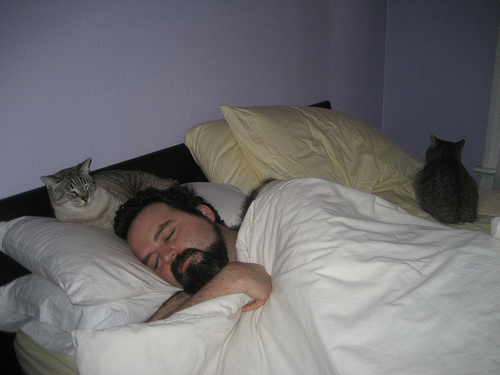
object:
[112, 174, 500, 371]
man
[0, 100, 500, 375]
bed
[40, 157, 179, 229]
cat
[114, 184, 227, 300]
head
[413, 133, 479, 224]
cat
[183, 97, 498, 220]
sheets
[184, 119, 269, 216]
pillows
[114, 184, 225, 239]
hair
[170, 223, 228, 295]
beard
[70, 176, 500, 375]
bed-cover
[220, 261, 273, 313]
hand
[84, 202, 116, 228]
belly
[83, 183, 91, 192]
eyes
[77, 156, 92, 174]
ear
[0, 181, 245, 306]
pillow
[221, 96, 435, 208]
pillowcase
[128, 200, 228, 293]
face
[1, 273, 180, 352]
pillow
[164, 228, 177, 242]
eye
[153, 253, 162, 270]
eye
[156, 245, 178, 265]
nose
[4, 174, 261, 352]
group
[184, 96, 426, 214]
group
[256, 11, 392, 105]
shadows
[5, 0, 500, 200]
wall